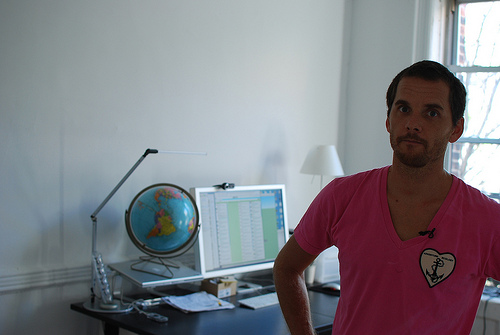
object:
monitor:
[197, 182, 293, 276]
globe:
[124, 185, 197, 258]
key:
[266, 293, 273, 301]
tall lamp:
[80, 140, 159, 310]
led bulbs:
[147, 148, 158, 154]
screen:
[175, 182, 305, 297]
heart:
[416, 246, 456, 288]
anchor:
[418, 248, 457, 286]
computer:
[182, 183, 306, 305]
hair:
[383, 58, 471, 120]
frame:
[199, 187, 291, 278]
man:
[272, 60, 499, 335]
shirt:
[294, 166, 498, 335]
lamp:
[300, 141, 348, 193]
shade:
[301, 141, 347, 178]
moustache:
[392, 132, 431, 150]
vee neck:
[376, 163, 460, 241]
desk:
[70, 278, 338, 333]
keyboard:
[237, 290, 277, 310]